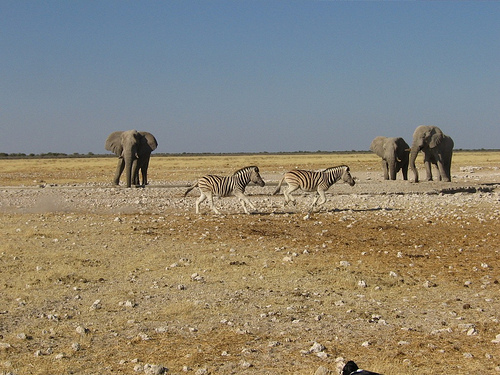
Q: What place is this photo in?
A: It is at the desert.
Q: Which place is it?
A: It is a desert.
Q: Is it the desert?
A: Yes, it is the desert.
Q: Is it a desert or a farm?
A: It is a desert.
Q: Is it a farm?
A: No, it is a desert.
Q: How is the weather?
A: It is clear.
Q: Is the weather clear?
A: Yes, it is clear.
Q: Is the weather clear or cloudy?
A: It is clear.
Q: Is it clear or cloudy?
A: It is clear.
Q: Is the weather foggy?
A: No, it is clear.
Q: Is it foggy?
A: No, it is clear.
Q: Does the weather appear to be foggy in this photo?
A: No, it is clear.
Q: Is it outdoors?
A: Yes, it is outdoors.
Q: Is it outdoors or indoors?
A: It is outdoors.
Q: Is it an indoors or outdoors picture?
A: It is outdoors.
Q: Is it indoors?
A: No, it is outdoors.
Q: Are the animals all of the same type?
A: No, there are both zebras and elephants.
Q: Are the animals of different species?
A: Yes, they are zebras and elephants.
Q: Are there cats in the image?
A: No, there are no cats.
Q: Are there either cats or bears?
A: No, there are no cats or bears.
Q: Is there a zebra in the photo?
A: Yes, there is a zebra.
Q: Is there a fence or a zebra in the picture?
A: Yes, there is a zebra.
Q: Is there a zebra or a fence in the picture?
A: Yes, there is a zebra.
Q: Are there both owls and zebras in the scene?
A: No, there is a zebra but no owls.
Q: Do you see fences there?
A: No, there are no fences.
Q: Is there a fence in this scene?
A: No, there are no fences.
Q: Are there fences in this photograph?
A: No, there are no fences.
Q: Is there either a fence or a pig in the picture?
A: No, there are no fences or pigs.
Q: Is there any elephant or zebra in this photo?
A: Yes, there is an elephant.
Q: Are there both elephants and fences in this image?
A: No, there is an elephant but no fences.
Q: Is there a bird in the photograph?
A: No, there are no birds.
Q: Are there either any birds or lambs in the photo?
A: No, there are no birds or lambs.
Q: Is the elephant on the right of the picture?
A: Yes, the elephant is on the right of the image.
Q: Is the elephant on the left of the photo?
A: No, the elephant is on the right of the image.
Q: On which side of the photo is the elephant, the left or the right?
A: The elephant is on the right of the image.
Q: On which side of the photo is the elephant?
A: The elephant is on the right of the image.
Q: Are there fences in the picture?
A: No, there are no fences.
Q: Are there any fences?
A: No, there are no fences.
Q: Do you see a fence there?
A: No, there are no fences.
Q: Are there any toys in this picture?
A: No, there are no toys.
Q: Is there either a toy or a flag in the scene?
A: No, there are no toys or flags.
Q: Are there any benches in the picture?
A: No, there are no benches.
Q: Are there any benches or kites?
A: No, there are no benches or kites.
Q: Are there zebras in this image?
A: Yes, there is a zebra.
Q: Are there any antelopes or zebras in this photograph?
A: Yes, there is a zebra.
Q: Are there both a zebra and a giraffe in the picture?
A: No, there is a zebra but no giraffes.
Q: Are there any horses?
A: No, there are no horses.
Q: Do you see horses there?
A: No, there are no horses.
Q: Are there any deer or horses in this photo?
A: No, there are no horses or deer.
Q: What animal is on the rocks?
A: The zebra is on the rocks.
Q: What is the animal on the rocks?
A: The animal is a zebra.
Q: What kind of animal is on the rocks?
A: The animal is a zebra.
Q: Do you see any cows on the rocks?
A: No, there is a zebra on the rocks.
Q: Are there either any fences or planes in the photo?
A: No, there are no fences or planes.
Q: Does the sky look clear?
A: Yes, the sky is clear.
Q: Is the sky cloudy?
A: No, the sky is clear.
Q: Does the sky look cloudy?
A: No, the sky is clear.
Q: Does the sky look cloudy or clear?
A: The sky is clear.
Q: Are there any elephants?
A: Yes, there are elephants.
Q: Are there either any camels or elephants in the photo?
A: Yes, there are elephants.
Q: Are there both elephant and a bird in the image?
A: No, there are elephants but no birds.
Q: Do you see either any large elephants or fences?
A: Yes, there are large elephants.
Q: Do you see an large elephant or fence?
A: Yes, there are large elephants.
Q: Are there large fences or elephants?
A: Yes, there are large elephants.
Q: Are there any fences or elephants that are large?
A: Yes, the elephants are large.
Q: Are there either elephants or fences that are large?
A: Yes, the elephants are large.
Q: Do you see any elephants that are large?
A: Yes, there are large elephants.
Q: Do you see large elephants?
A: Yes, there are large elephants.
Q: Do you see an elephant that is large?
A: Yes, there are elephants that are large.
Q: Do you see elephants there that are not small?
A: Yes, there are large elephants.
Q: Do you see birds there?
A: No, there are no birds.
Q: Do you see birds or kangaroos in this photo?
A: No, there are no birds or kangaroos.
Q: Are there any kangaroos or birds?
A: No, there are no birds or kangaroos.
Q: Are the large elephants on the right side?
A: Yes, the elephants are on the right of the image.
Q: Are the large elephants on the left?
A: No, the elephants are on the right of the image.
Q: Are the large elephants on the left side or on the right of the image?
A: The elephants are on the right of the image.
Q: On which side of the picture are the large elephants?
A: The elephants are on the right of the image.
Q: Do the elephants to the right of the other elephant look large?
A: Yes, the elephants are large.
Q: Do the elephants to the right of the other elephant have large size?
A: Yes, the elephants are large.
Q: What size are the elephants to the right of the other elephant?
A: The elephants are large.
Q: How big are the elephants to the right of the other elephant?
A: The elephants are large.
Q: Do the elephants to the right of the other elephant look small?
A: No, the elephants are large.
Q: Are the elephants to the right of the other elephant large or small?
A: The elephants are large.